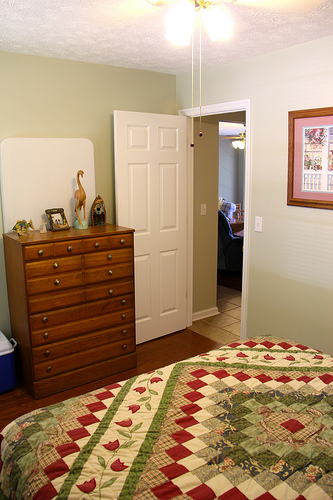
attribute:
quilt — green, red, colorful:
[9, 337, 332, 500]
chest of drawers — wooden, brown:
[10, 230, 136, 385]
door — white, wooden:
[114, 110, 187, 342]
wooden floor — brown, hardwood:
[4, 330, 241, 399]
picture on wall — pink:
[293, 112, 331, 204]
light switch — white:
[253, 216, 263, 232]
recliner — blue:
[213, 212, 242, 278]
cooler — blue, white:
[2, 334, 21, 385]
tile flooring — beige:
[202, 300, 244, 341]